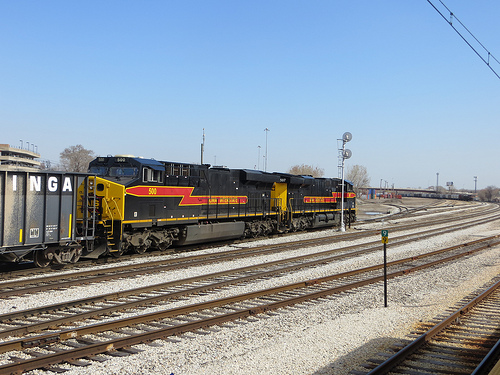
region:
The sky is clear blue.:
[3, 1, 498, 158]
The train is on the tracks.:
[65, 145, 372, 249]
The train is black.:
[73, 145, 328, 235]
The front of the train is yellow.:
[68, 173, 124, 241]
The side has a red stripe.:
[120, 178, 257, 211]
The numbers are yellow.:
[139, 185, 157, 194]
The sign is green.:
[375, 224, 390, 245]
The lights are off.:
[339, 128, 356, 168]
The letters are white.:
[7, 167, 69, 194]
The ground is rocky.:
[140, 282, 377, 374]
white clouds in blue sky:
[4, 11, 44, 46]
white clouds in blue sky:
[39, 35, 87, 75]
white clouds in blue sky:
[102, 71, 167, 115]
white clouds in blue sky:
[174, 78, 251, 124]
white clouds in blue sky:
[234, 63, 294, 127]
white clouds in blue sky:
[266, 51, 323, 90]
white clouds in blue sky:
[351, 73, 411, 122]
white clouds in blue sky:
[383, 101, 438, 145]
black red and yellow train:
[77, 161, 334, 242]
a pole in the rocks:
[366, 215, 402, 310]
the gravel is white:
[345, 306, 400, 331]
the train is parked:
[70, 150, 370, 240]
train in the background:
[355, 165, 480, 205]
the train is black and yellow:
[67, 155, 367, 233]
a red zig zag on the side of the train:
[117, 155, 256, 229]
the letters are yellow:
[195, 187, 245, 210]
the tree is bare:
[330, 152, 387, 205]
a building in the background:
[0, 128, 47, 171]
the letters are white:
[4, 156, 77, 203]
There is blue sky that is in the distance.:
[363, 57, 423, 151]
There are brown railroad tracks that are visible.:
[253, 283, 299, 337]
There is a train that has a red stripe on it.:
[167, 155, 209, 218]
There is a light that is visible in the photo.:
[336, 129, 371, 189]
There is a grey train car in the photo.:
[22, 199, 45, 236]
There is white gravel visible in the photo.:
[293, 340, 318, 374]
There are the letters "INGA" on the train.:
[8, 168, 83, 203]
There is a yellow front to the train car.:
[86, 173, 107, 226]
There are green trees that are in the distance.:
[62, 145, 87, 181]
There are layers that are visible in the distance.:
[4, 134, 25, 166]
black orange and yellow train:
[105, 167, 330, 229]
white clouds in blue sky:
[17, 17, 107, 94]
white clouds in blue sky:
[55, 84, 85, 128]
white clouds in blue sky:
[131, 45, 162, 99]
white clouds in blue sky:
[184, 48, 240, 124]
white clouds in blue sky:
[227, 22, 262, 67]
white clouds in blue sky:
[240, 81, 276, 111]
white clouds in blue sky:
[261, 10, 308, 82]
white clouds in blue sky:
[343, 62, 380, 99]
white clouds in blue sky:
[364, 101, 421, 143]